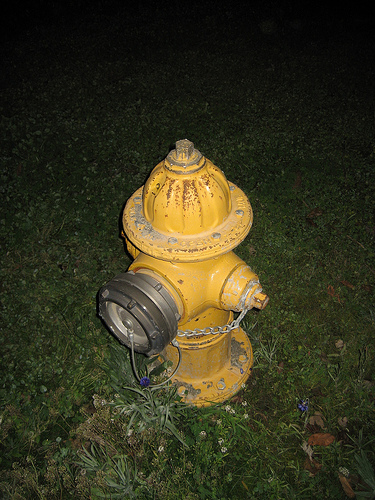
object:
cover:
[119, 135, 254, 265]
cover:
[96, 271, 180, 355]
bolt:
[214, 378, 227, 393]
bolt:
[211, 227, 222, 242]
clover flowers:
[196, 425, 208, 442]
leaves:
[336, 469, 356, 498]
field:
[258, 53, 374, 263]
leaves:
[336, 413, 350, 432]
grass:
[256, 332, 288, 380]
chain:
[175, 304, 249, 344]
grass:
[19, 123, 97, 241]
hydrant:
[97, 138, 269, 413]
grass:
[22, 395, 57, 458]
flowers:
[294, 394, 312, 415]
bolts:
[233, 206, 245, 219]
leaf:
[305, 430, 338, 449]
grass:
[315, 445, 345, 461]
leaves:
[308, 401, 329, 431]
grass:
[151, 14, 201, 110]